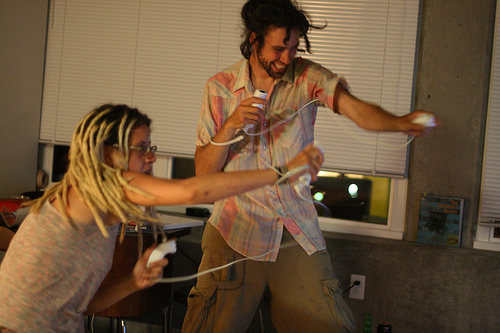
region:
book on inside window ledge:
[415, 193, 464, 245]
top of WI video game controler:
[253, 89, 266, 97]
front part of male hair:
[283, 27, 292, 44]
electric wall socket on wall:
[346, 273, 368, 299]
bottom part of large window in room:
[318, 176, 405, 228]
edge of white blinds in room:
[329, 148, 411, 176]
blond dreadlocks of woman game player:
[72, 165, 118, 231]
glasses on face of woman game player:
[139, 145, 158, 152]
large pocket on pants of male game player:
[321, 278, 356, 329]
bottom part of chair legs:
[88, 314, 168, 330]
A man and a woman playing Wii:
[56, 2, 368, 299]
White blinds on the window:
[41, 7, 230, 89]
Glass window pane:
[312, 180, 379, 212]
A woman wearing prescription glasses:
[51, 68, 198, 250]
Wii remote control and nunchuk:
[234, 72, 462, 150]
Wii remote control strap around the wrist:
[201, 85, 273, 159]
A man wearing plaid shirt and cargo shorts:
[203, 2, 388, 331]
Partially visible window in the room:
[476, 0, 496, 274]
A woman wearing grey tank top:
[1, 99, 177, 323]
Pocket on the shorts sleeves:
[313, 263, 360, 328]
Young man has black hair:
[179, 1, 439, 332]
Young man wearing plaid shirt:
[181, 0, 443, 331]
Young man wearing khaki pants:
[177, 1, 440, 331]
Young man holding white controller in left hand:
[190, 0, 440, 331]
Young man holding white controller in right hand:
[190, 0, 435, 330]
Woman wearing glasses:
[1, 101, 325, 332]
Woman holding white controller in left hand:
[0, 95, 325, 330]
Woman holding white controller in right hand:
[0, 100, 325, 330]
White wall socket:
[348, 274, 366, 303]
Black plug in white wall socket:
[339, 273, 367, 305]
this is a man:
[180, 6, 365, 159]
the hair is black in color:
[249, 7, 297, 24]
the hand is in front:
[339, 97, 442, 137]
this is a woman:
[3, 99, 177, 322]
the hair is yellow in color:
[67, 148, 102, 188]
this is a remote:
[406, 114, 438, 126]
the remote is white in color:
[413, 113, 430, 125]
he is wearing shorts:
[238, 270, 316, 320]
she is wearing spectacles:
[139, 142, 159, 153]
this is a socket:
[344, 275, 366, 302]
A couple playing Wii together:
[55, 20, 465, 316]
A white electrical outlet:
[344, 272, 371, 299]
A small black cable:
[339, 280, 363, 297]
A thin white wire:
[177, 237, 299, 280]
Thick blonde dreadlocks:
[56, 115, 149, 229]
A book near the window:
[415, 191, 467, 248]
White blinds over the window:
[59, 0, 421, 165]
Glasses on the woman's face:
[121, 138, 168, 160]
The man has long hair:
[231, 1, 326, 50]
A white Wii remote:
[241, 84, 270, 141]